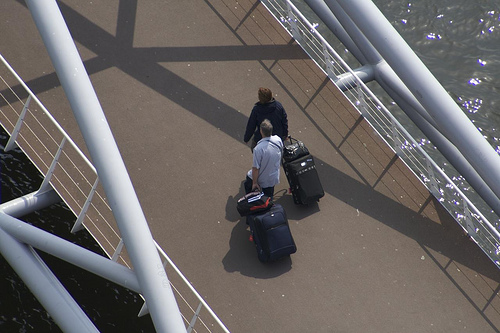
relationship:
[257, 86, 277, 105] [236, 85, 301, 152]
head of a man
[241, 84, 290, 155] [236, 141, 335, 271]
man with suitcases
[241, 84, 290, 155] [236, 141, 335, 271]
man walking with luggage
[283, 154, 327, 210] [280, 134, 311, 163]
suitcase with purse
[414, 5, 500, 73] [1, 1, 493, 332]
water below bridge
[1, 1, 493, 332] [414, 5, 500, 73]
bridge crossing water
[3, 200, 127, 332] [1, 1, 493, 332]
poles supporting bridge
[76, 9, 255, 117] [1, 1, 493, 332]
shadows of bridge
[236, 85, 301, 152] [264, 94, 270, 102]
woman with red hair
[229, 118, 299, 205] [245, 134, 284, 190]
man wearing a shirt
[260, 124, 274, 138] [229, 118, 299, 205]
head of a man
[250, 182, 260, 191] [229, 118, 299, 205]
hand of a man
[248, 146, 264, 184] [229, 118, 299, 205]
arm of a man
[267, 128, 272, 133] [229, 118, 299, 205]
hair of a man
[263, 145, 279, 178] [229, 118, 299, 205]
back of a man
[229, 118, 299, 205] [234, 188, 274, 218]
man with a tote bag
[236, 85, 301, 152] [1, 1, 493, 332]
man walking on a bridge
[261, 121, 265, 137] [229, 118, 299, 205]
face of a man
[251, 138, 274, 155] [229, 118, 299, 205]
shoulder of a man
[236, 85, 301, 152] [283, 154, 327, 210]
man dragging a suitcase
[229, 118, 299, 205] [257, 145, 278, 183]
man wearing a shirt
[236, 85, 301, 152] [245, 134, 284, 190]
man wearing a shirt